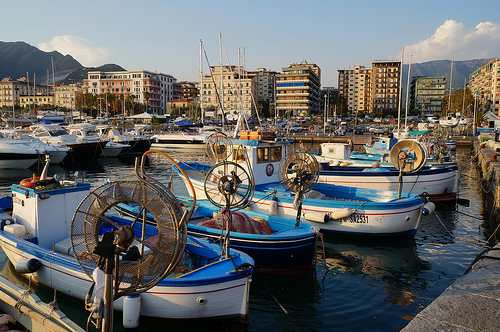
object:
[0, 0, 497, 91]
sky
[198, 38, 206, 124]
masts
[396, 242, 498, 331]
grey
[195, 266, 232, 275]
dark blue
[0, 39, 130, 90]
mountain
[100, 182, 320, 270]
blue boat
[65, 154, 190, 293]
fan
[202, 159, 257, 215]
fan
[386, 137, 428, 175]
fan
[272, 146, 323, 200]
fan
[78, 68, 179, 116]
buildings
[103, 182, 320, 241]
bed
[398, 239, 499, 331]
sidewalk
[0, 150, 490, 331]
water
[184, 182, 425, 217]
stripe